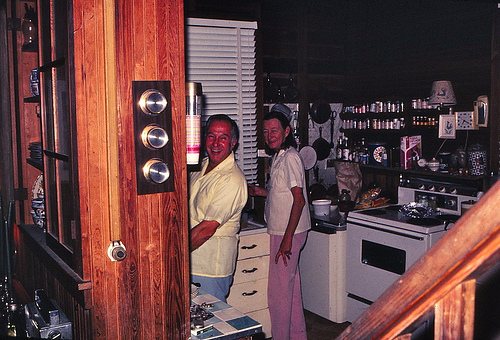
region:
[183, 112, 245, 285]
older man with yellow shirt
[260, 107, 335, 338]
older woman with pink pants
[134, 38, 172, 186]
three small round clocks on wall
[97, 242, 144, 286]
small thermostat dial on wall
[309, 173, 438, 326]
white and black stove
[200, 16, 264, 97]
white horizontal window blinds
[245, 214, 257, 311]
cream colored cabinets with black handles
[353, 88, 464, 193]
shelf wall of seasonings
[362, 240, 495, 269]
light wooden bannister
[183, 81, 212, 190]
a cup dispener on wall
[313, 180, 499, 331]
brown wooden rail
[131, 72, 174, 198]
barometer on wall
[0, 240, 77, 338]
trophies on floor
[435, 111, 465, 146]
blue and white picture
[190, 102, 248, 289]
guy in white shirt smiling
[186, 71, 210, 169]
dixie cup holder with pink cups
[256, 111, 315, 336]
woman smiling while looking at camera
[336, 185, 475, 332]
white stove with oven window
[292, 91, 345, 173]
group of pots and pans hanging on wall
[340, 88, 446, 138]
spices up on a shelf next to stove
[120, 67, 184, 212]
gauges on the wall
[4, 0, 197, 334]
wooden cabinet with shelves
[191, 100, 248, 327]
smiling man in a kitchen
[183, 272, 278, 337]
white and blue tiles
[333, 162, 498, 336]
white oven with black stove top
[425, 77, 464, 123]
white lampshade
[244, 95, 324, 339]
woman wearing white shirt and pink pants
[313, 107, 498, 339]
wooden railing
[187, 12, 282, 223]
white blinds cover the window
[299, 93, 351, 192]
pots and utensils on the wall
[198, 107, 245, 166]
the head of a man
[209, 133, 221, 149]
the nose of a man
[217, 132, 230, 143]
the eye of a man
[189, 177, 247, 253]
the arm of a man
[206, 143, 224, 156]
the mouth of a man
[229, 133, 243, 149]
the ear of a man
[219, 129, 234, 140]
the eyebrow of a man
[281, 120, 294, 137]
the ear of a woman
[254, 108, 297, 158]
the head of a woman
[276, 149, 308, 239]
the arm of a woman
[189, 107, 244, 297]
man wearing a white shirt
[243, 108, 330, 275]
woman wearing a white shirt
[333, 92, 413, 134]
spice bottles on a shelf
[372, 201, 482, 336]
wooden stairway bannister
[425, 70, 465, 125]
white wall lamp over the stove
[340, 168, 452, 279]
black and white oven with range top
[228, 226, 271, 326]
white wooden kitchen drawers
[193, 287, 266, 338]
blue and white tile counter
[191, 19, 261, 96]
white mini blinds on window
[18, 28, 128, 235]
wooden shelves and room divider